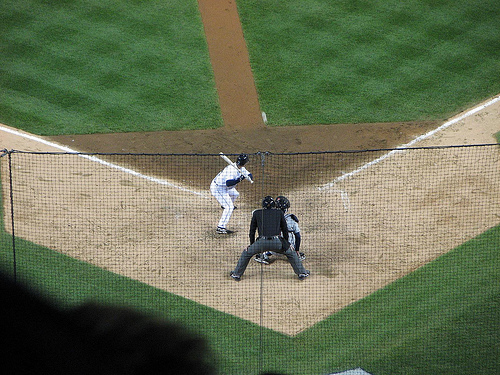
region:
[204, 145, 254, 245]
a man playing cricket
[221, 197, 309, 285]
a man playing cricket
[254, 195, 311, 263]
a man playing cricket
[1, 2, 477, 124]
the ground is green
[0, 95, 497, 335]
the ground is brown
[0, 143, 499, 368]
the net is black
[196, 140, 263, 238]
the player in white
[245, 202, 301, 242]
the player in black shirt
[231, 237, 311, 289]
the player in grey pants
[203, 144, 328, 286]
the players are wearing helmets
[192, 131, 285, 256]
the batter is up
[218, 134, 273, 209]
the bat is white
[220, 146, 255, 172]
the man is wearing the helmet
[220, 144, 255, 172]
the helmet is black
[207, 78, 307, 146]
the ball is moving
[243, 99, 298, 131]
the ball is in the air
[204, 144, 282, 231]
the player`s uniform is white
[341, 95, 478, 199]
the line on the ground is white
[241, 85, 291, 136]
the ball is white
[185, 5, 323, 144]
the dirt is brown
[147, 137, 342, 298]
baseball players on a field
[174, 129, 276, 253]
baseball player with his bat ready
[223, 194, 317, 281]
catcher kneeling for ball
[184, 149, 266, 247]
man in white uniform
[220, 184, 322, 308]
man wearing a black uniform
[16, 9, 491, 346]
baseball field with grass and sand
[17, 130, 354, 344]
sand path through the field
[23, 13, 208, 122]
grass mowed in a checkered pattern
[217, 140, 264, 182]
black baseball helmet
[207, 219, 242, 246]
black and white sneakers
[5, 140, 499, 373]
black fence behind batting area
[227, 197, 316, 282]
umpire stands with legs apart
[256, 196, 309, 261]
catcher stands in front of umpire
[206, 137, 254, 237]
man in white about to hit the baseball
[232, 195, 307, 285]
umpire in black shirt and gray pants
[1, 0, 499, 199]
grass mowed with square patterns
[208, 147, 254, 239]
white uniform with black sleeves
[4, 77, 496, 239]
white lines in field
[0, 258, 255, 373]
partial view of spectator's hair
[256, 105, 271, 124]
white baseball flying in air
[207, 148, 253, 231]
batter about to hit baseball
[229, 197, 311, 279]
umpire bending over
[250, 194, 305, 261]
catcher getting ready to catch baseball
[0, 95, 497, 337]
dirt area of baseball diamond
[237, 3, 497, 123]
green turf area of baseball field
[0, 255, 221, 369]
shadow area on baseball field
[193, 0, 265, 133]
dirt area leading to pitcher's mound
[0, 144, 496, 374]
netting behind baseball field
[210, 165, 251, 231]
white baseball uniform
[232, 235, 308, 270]
gray pants on umpire